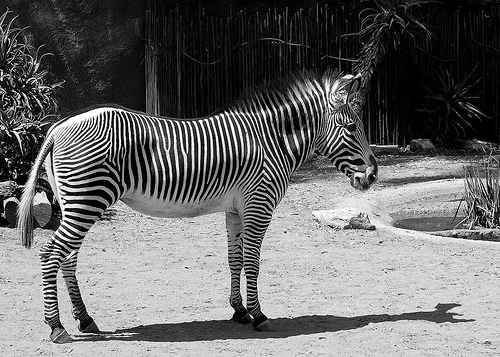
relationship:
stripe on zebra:
[47, 220, 81, 232] [42, 87, 404, 334]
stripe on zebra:
[60, 201, 90, 256] [16, 64, 381, 352]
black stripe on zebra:
[63, 197, 108, 208] [16, 64, 381, 352]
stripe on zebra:
[276, 91, 304, 167] [16, 64, 381, 352]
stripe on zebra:
[333, 156, 366, 173] [16, 64, 381, 352]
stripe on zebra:
[326, 151, 351, 162] [16, 64, 381, 352]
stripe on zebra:
[224, 108, 240, 191] [16, 64, 381, 352]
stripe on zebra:
[192, 120, 204, 212] [16, 64, 381, 352]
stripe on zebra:
[61, 196, 108, 211] [16, 64, 381, 352]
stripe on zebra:
[275, 96, 300, 162] [16, 64, 381, 352]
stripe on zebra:
[58, 177, 126, 199] [16, 64, 381, 352]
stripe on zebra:
[61, 201, 106, 221] [16, 64, 381, 352]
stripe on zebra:
[39, 280, 61, 295] [16, 64, 381, 352]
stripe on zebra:
[240, 262, 257, 278] [16, 64, 381, 352]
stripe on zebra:
[51, 234, 74, 254] [16, 64, 381, 352]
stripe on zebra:
[50, 226, 84, 236] [80, 48, 422, 337]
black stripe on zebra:
[63, 206, 100, 218] [16, 64, 381, 352]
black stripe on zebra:
[61, 199, 106, 209] [16, 64, 381, 352]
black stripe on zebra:
[59, 187, 113, 202] [16, 64, 381, 352]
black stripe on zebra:
[57, 179, 119, 198] [16, 64, 381, 352]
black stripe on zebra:
[49, 162, 124, 194] [16, 64, 381, 352]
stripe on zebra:
[52, 187, 127, 196] [16, 64, 381, 352]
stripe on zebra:
[328, 140, 358, 155] [16, 64, 381, 352]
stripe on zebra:
[59, 209, 90, 238] [17, 76, 398, 318]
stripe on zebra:
[197, 123, 210, 208] [16, 64, 381, 352]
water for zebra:
[395, 181, 472, 242] [53, 85, 390, 283]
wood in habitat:
[1, 181, 62, 229] [4, 3, 495, 351]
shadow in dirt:
[72, 289, 490, 343] [92, 250, 209, 335]